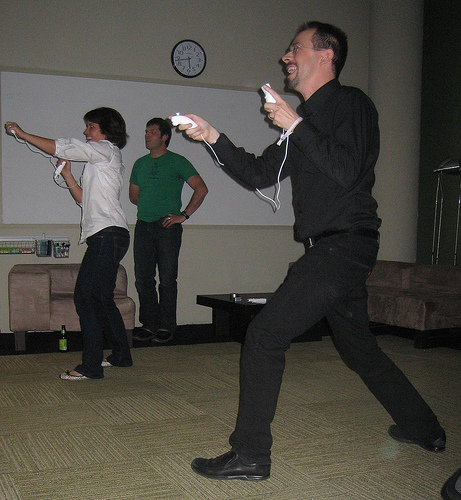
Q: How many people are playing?
A: Two.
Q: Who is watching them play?
A: Man in green shirt.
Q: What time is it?
A: 5:45.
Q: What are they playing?
A: The Wii.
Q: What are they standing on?
A: Carpet.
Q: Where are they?
A: Classroom.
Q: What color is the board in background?
A: White.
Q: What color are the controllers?
A: White.